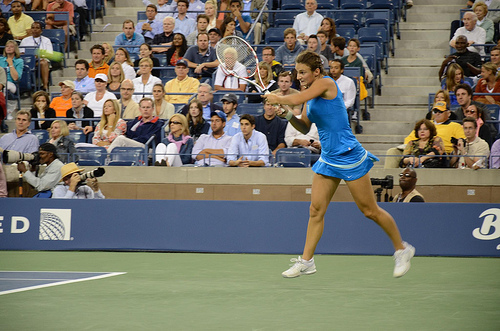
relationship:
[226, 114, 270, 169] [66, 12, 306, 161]
man in stands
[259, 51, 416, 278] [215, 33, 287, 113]
woman holding racket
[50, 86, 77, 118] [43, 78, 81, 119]
shirt on man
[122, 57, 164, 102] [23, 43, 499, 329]
person sitting watching tennis game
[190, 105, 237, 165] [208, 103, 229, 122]
man wearing blue cap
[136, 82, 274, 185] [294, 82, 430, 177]
man wearing shirt